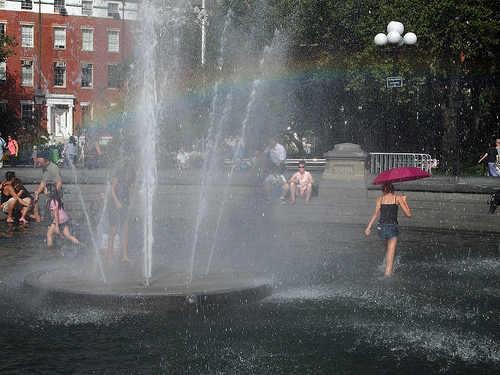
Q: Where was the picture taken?
A: It was taken at the swimming pool.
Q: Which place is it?
A: It is a swimming pool.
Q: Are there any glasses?
A: No, there are no glasses.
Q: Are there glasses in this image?
A: No, there are no glasses.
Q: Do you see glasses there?
A: No, there are no glasses.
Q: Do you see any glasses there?
A: No, there are no glasses.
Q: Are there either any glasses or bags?
A: No, there are no glasses or bags.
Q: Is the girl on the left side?
A: Yes, the girl is on the left of the image.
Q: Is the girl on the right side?
A: No, the girl is on the left of the image.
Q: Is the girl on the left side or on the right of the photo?
A: The girl is on the left of the image.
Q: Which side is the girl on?
A: The girl is on the left of the image.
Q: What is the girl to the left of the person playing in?
A: The girl is playing in the water.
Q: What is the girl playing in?
A: The girl is playing in the water.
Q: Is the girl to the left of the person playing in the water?
A: Yes, the girl is playing in the water.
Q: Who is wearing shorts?
A: The girl is wearing shorts.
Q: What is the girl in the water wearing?
A: The girl is wearing shorts.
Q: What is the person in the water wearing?
A: The girl is wearing shorts.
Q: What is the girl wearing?
A: The girl is wearing shorts.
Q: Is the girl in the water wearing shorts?
A: Yes, the girl is wearing shorts.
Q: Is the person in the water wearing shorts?
A: Yes, the girl is wearing shorts.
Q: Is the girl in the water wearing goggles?
A: No, the girl is wearing shorts.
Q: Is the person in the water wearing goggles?
A: No, the girl is wearing shorts.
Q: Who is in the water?
A: The girl is in the water.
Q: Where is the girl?
A: The girl is in the water.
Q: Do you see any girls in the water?
A: Yes, there is a girl in the water.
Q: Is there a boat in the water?
A: No, there is a girl in the water.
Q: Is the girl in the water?
A: Yes, the girl is in the water.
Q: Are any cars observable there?
A: No, there are no cars.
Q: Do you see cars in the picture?
A: No, there are no cars.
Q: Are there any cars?
A: No, there are no cars.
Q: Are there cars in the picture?
A: No, there are no cars.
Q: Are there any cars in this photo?
A: No, there are no cars.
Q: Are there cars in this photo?
A: No, there are no cars.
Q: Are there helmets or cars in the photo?
A: No, there are no cars or helmets.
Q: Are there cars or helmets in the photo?
A: No, there are no cars or helmets.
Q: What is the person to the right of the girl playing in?
A: The person is playing in the water.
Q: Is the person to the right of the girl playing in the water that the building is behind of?
A: Yes, the person is playing in the water.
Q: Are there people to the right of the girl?
A: Yes, there is a person to the right of the girl.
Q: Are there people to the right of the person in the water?
A: Yes, there is a person to the right of the girl.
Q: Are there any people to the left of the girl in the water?
A: No, the person is to the right of the girl.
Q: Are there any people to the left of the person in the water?
A: No, the person is to the right of the girl.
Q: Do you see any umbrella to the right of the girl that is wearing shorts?
A: No, there is a person to the right of the girl.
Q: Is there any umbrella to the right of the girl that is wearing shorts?
A: No, there is a person to the right of the girl.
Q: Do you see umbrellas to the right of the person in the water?
A: No, there is a person to the right of the girl.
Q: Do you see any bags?
A: No, there are no bags.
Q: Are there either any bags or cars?
A: No, there are no bags or cars.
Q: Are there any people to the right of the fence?
A: No, the person is to the left of the fence.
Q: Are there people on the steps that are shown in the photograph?
A: Yes, there is a person on the steps.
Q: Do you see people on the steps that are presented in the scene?
A: Yes, there is a person on the steps.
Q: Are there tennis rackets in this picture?
A: No, there are no tennis rackets.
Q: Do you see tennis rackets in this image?
A: No, there are no tennis rackets.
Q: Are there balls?
A: No, there are no balls.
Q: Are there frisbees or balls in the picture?
A: No, there are no balls or frisbees.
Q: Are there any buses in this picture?
A: No, there are no buses.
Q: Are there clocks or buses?
A: No, there are no buses or clocks.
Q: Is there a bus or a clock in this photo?
A: No, there are no buses or clocks.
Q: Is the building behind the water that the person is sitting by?
A: Yes, the building is behind the water.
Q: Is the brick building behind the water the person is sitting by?
A: Yes, the building is behind the water.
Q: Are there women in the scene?
A: Yes, there is a woman.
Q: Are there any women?
A: Yes, there is a woman.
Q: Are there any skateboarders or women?
A: Yes, there is a woman.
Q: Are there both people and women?
A: Yes, there are both a woman and people.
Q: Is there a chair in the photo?
A: No, there are no chairs.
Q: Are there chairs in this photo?
A: No, there are no chairs.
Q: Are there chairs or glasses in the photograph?
A: No, there are no chairs or glasses.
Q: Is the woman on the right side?
A: Yes, the woman is on the right of the image.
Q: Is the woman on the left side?
A: No, the woman is on the right of the image.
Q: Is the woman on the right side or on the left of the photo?
A: The woman is on the right of the image.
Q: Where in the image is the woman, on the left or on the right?
A: The woman is on the right of the image.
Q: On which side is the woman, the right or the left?
A: The woman is on the right of the image.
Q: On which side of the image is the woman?
A: The woman is on the right of the image.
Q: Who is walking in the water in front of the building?
A: The woman is walking in the water.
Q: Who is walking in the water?
A: The woman is walking in the water.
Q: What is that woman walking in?
A: The woman is walking in the water.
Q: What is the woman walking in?
A: The woman is walking in the water.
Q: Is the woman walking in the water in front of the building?
A: Yes, the woman is walking in the water.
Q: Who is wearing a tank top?
A: The woman is wearing a tank top.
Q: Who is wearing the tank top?
A: The woman is wearing a tank top.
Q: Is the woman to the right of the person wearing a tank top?
A: Yes, the woman is wearing a tank top.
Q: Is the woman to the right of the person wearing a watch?
A: No, the woman is wearing a tank top.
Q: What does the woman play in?
A: The woman plays in the water.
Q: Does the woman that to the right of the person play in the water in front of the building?
A: Yes, the woman plays in the water.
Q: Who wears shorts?
A: The woman wears shorts.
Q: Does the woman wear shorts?
A: Yes, the woman wears shorts.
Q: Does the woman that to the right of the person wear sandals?
A: No, the woman wears shorts.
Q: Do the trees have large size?
A: Yes, the trees are large.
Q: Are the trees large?
A: Yes, the trees are large.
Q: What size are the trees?
A: The trees are large.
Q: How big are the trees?
A: The trees are large.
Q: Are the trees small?
A: No, the trees are large.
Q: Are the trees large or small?
A: The trees are large.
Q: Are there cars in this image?
A: No, there are no cars.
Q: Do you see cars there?
A: No, there are no cars.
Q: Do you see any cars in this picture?
A: No, there are no cars.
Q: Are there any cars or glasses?
A: No, there are no cars or glasses.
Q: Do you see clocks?
A: No, there are no clocks.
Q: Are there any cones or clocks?
A: No, there are no clocks or cones.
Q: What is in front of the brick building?
A: The water is in front of the building.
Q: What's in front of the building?
A: The water is in front of the building.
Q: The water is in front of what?
A: The water is in front of the building.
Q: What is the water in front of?
A: The water is in front of the building.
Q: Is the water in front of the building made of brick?
A: Yes, the water is in front of the building.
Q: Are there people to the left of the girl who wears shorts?
A: Yes, there are people to the left of the girl.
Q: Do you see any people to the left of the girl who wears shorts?
A: Yes, there are people to the left of the girl.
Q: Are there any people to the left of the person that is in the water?
A: Yes, there are people to the left of the girl.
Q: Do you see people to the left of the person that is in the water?
A: Yes, there are people to the left of the girl.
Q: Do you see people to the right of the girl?
A: No, the people are to the left of the girl.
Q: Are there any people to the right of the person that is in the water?
A: No, the people are to the left of the girl.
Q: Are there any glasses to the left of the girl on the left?
A: No, there are people to the left of the girl.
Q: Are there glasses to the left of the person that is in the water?
A: No, there are people to the left of the girl.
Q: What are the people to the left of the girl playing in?
A: The people are playing in the water.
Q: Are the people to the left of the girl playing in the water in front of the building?
A: Yes, the people are playing in the water.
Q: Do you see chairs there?
A: No, there are no chairs.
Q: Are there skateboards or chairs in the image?
A: No, there are no chairs or skateboards.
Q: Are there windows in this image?
A: Yes, there are windows.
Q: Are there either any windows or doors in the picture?
A: Yes, there are windows.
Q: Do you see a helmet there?
A: No, there are no helmets.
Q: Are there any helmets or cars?
A: No, there are no helmets or cars.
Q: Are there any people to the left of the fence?
A: Yes, there is a person to the left of the fence.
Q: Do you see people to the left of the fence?
A: Yes, there is a person to the left of the fence.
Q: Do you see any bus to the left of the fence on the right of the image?
A: No, there is a person to the left of the fence.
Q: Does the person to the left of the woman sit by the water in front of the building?
A: Yes, the person sits by the water.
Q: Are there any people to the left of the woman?
A: Yes, there is a person to the left of the woman.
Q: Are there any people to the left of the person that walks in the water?
A: Yes, there is a person to the left of the woman.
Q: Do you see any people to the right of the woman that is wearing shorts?
A: No, the person is to the left of the woman.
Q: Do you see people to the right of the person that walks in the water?
A: No, the person is to the left of the woman.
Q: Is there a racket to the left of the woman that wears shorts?
A: No, there is a person to the left of the woman.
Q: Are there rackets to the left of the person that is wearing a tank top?
A: No, there is a person to the left of the woman.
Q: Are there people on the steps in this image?
A: Yes, there is a person on the steps.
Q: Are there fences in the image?
A: Yes, there is a fence.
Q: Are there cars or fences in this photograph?
A: Yes, there is a fence.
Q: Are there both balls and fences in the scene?
A: No, there is a fence but no balls.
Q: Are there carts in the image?
A: No, there are no carts.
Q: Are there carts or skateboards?
A: No, there are no carts or skateboards.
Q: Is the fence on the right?
A: Yes, the fence is on the right of the image.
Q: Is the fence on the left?
A: No, the fence is on the right of the image.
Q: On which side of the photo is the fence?
A: The fence is on the right of the image.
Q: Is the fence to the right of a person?
A: Yes, the fence is to the right of a person.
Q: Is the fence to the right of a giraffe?
A: No, the fence is to the right of a person.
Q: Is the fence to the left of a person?
A: No, the fence is to the right of a person.